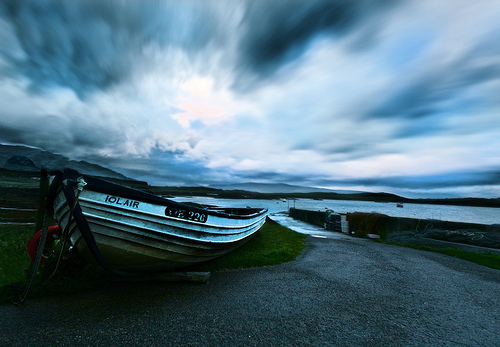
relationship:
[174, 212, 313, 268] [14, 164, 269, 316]
grass under a boat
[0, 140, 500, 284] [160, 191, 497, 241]
boat in water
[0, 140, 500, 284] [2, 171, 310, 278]
boat in grass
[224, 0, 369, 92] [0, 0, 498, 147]
cloud in sky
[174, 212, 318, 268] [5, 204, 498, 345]
grass near road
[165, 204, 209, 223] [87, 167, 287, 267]
number on boat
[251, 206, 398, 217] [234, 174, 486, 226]
dock to lake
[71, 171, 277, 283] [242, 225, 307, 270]
boat on grass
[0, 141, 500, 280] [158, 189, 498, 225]
hills by lake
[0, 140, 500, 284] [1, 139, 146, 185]
boat behind mountain range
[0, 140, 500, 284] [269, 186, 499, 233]
boat out on water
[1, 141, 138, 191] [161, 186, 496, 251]
hills leading to water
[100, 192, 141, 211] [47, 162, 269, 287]
name on boat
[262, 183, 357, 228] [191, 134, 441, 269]
lack in front hills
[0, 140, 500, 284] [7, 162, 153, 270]
boat behind car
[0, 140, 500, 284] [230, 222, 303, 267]
boat over grass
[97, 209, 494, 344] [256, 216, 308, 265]
path next grass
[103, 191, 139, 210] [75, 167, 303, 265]
letters on boat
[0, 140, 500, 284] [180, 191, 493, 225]
boat in water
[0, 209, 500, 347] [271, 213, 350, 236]
path in front of ramp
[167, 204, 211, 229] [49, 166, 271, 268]
number of boat